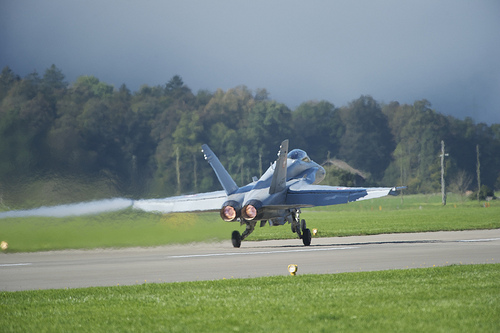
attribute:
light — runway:
[289, 263, 297, 274]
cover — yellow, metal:
[288, 264, 298, 274]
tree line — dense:
[1, 57, 499, 200]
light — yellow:
[282, 262, 302, 277]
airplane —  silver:
[123, 132, 399, 252]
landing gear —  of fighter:
[227, 220, 332, 248]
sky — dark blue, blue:
[0, 1, 498, 126]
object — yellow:
[287, 258, 302, 279]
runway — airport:
[2, 238, 298, 276]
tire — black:
[231, 228, 243, 248]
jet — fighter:
[154, 132, 426, 263]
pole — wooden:
[436, 137, 455, 207]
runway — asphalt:
[3, 244, 435, 277]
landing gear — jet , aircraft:
[231, 220, 311, 247]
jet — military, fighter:
[129, 117, 412, 250]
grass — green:
[0, 262, 498, 331]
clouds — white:
[106, 15, 130, 35]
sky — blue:
[0, 2, 497, 139]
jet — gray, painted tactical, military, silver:
[134, 137, 406, 246]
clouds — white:
[191, 18, 360, 100]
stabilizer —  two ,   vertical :
[193, 139, 308, 233]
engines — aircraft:
[217, 200, 264, 222]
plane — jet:
[136, 119, 405, 257]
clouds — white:
[10, 3, 455, 98]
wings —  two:
[101, 182, 428, 211]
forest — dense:
[6, 71, 497, 215]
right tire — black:
[299, 223, 319, 248]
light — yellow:
[249, 252, 339, 314]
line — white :
[1, 237, 499, 266]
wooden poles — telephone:
[438, 135, 454, 222]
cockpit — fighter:
[287, 146, 301, 161]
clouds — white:
[76, 0, 498, 90]